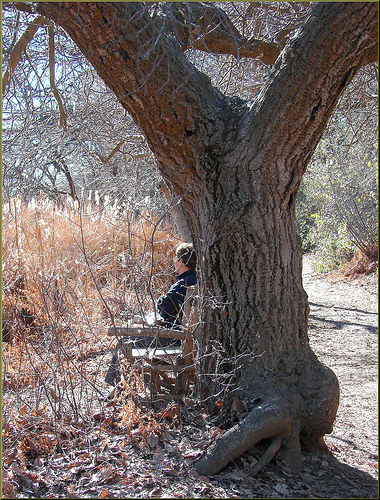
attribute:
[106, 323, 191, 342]
arm — wooden 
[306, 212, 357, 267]
bush — green 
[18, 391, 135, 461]
grass — DEAD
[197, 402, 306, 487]
tree roots — large 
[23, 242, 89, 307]
grass — dead 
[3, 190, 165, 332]
grass — dead 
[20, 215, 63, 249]
grass — dead 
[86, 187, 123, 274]
what — tall 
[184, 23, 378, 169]
limbs — tree limbs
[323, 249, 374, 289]
grass — dead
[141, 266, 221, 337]
shirt — blue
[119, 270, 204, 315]
jacket — blue 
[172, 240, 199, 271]
hair — brown 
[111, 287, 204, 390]
bench — wooden 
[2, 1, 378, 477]
tree — large 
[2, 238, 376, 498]
grass — dead 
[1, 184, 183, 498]
grass — dead 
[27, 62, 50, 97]
sky — blue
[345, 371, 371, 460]
grass — dead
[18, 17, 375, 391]
tree — bare